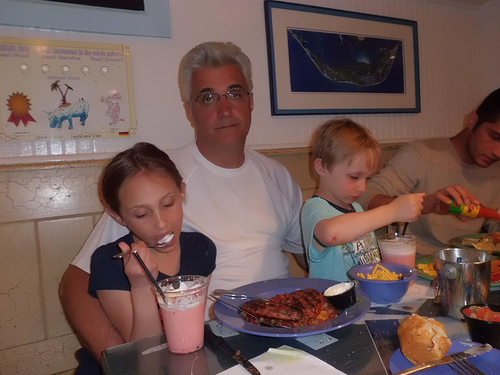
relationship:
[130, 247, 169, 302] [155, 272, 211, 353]
straw inside of milkshake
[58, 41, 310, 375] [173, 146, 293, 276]
man wearing shirt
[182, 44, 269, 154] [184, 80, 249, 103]
man wearing glasses